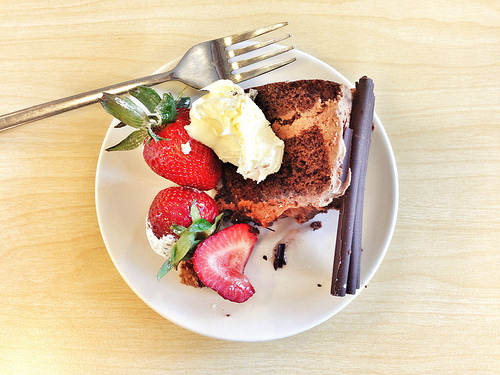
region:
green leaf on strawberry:
[103, 128, 145, 155]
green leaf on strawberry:
[99, 91, 146, 131]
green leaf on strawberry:
[113, 115, 126, 127]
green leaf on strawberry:
[127, 83, 154, 112]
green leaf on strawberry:
[138, 85, 161, 105]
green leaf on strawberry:
[153, 91, 173, 122]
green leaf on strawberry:
[171, 227, 196, 262]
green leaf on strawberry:
[183, 216, 212, 233]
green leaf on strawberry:
[188, 199, 205, 218]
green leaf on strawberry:
[157, 260, 172, 279]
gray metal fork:
[0, 18, 296, 130]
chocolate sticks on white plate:
[331, 74, 378, 295]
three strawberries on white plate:
[140, 106, 254, 302]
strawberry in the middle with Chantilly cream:
[144, 185, 212, 265]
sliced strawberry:
[191, 224, 255, 301]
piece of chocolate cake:
[225, 80, 346, 224]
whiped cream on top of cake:
[186, 79, 286, 183]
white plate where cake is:
[93, 40, 395, 346]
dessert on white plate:
[133, 66, 378, 309]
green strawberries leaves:
[93, 84, 220, 282]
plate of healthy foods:
[108, 69, 395, 319]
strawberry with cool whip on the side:
[130, 188, 220, 263]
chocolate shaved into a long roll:
[331, 82, 375, 312]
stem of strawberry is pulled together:
[97, 88, 224, 188]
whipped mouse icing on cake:
[276, 76, 350, 214]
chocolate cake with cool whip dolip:
[225, 80, 348, 220]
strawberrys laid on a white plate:
[131, 86, 258, 305]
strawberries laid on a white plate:
[139, 98, 251, 320]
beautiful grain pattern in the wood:
[3, 155, 96, 355]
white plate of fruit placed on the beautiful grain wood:
[58, 92, 427, 365]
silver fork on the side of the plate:
[0, 21, 295, 131]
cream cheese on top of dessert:
[188, 81, 284, 178]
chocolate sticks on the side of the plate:
[330, 77, 375, 295]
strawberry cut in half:
[193, 223, 258, 303]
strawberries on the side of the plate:
[100, 88, 260, 305]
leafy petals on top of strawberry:
[98, 86, 188, 154]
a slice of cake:
[218, 81, 351, 225]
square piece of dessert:
[216, 78, 351, 229]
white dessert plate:
[96, 44, 397, 344]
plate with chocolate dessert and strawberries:
[95, 40, 397, 341]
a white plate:
[96, 45, 396, 342]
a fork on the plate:
[2, 22, 283, 119]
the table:
[2, 5, 493, 370]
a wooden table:
[7, 3, 482, 368]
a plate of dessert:
[121, 40, 413, 333]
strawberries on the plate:
[141, 109, 259, 294]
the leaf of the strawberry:
[99, 82, 176, 150]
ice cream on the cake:
[196, 78, 281, 176]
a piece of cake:
[223, 80, 340, 221]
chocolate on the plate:
[336, 76, 369, 298]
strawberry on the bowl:
[188, 253, 250, 303]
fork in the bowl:
[186, 20, 290, 82]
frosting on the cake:
[202, 118, 277, 168]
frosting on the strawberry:
[137, 225, 173, 254]